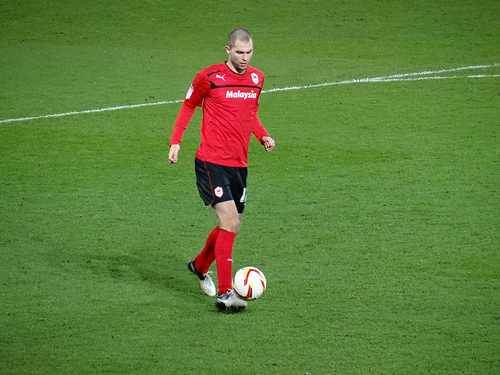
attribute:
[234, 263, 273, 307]
white — red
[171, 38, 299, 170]
man — kicking